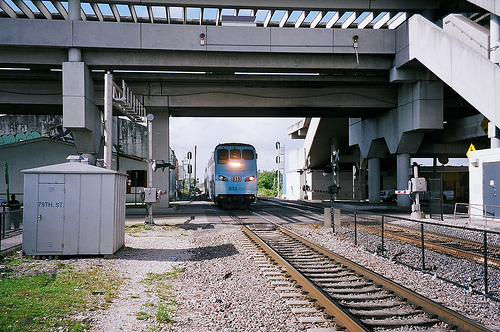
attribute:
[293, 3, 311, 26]
beam — silver, metal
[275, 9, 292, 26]
beam — metal, silver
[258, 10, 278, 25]
beam — metal, silver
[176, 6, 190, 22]
beam — metal, silver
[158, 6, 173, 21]
beam — metal, silver